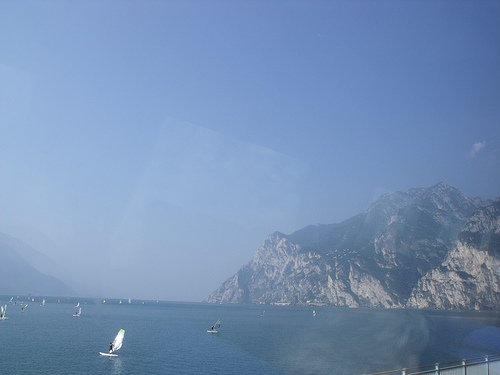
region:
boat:
[81, 321, 146, 368]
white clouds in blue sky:
[268, 41, 308, 85]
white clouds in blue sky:
[382, 76, 424, 93]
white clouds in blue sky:
[182, 75, 219, 116]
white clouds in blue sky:
[234, 165, 275, 223]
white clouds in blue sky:
[120, 71, 154, 126]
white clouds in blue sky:
[81, 188, 161, 253]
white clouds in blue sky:
[155, 73, 196, 125]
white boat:
[93, 314, 126, 365]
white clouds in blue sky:
[80, 132, 120, 163]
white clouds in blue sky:
[285, 139, 325, 167]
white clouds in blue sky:
[101, 161, 138, 205]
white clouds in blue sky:
[121, 108, 176, 146]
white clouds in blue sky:
[34, 176, 111, 231]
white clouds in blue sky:
[282, 73, 312, 88]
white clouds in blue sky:
[170, 58, 215, 96]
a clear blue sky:
[6, 2, 457, 160]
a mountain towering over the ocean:
[201, 148, 494, 331]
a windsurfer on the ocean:
[87, 323, 132, 359]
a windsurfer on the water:
[201, 317, 232, 337]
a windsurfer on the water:
[66, 306, 87, 325]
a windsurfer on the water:
[308, 305, 325, 322]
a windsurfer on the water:
[20, 298, 33, 314]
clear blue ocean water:
[245, 318, 417, 365]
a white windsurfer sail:
[105, 324, 132, 354]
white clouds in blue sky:
[92, 109, 120, 154]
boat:
[74, 306, 152, 368]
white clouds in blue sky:
[111, 69, 139, 121]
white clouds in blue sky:
[88, 188, 153, 230]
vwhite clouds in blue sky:
[190, 51, 265, 106]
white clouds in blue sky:
[367, 71, 405, 116]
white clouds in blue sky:
[114, 193, 154, 224]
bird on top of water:
[99, 328, 134, 359]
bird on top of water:
[197, 321, 228, 348]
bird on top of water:
[36, 296, 56, 316]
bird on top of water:
[19, 301, 39, 319]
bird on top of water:
[113, 296, 124, 307]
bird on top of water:
[126, 296, 138, 306]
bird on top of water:
[137, 295, 159, 313]